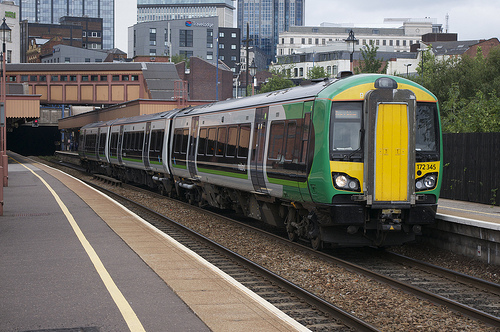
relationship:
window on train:
[331, 100, 365, 152] [82, 72, 439, 249]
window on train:
[416, 102, 439, 155] [82, 72, 439, 249]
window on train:
[269, 122, 286, 162] [82, 72, 439, 249]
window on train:
[237, 124, 254, 159] [82, 72, 439, 249]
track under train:
[59, 158, 499, 324] [82, 72, 439, 249]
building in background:
[128, 18, 219, 77] [5, 0, 499, 149]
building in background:
[62, 15, 104, 60] [5, 0, 499, 149]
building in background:
[271, 51, 353, 80] [5, 0, 499, 149]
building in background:
[0, 0, 22, 66] [5, 0, 499, 149]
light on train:
[334, 176, 347, 187] [82, 72, 439, 249]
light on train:
[349, 182, 359, 192] [82, 72, 439, 249]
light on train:
[415, 182, 423, 190] [82, 72, 439, 249]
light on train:
[425, 174, 437, 187] [82, 72, 439, 249]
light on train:
[377, 77, 394, 89] [82, 72, 439, 249]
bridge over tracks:
[0, 64, 187, 103] [21, 160, 380, 329]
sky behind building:
[3, 0, 499, 51] [128, 18, 219, 77]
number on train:
[416, 164, 437, 171] [82, 72, 439, 249]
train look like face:
[82, 72, 439, 249] [331, 169, 440, 206]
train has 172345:
[82, 72, 439, 249] [416, 164, 437, 171]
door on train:
[376, 103, 408, 200] [82, 72, 439, 249]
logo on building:
[184, 21, 194, 27] [128, 18, 219, 77]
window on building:
[149, 28, 159, 48] [128, 18, 219, 77]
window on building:
[93, 29, 98, 40] [62, 15, 104, 60]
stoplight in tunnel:
[33, 119, 40, 125] [6, 125, 62, 156]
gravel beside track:
[21, 160, 380, 329] [59, 158, 499, 324]